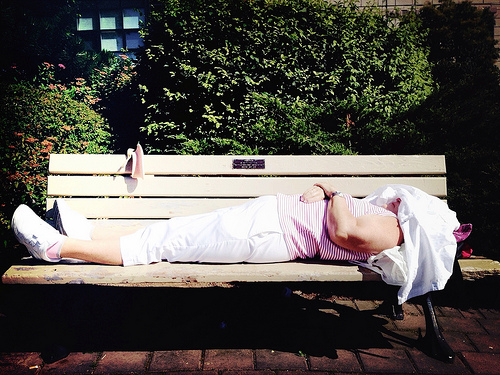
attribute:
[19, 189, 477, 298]
woman — resting, sleeping, tired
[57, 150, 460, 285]
bench — beige, wooden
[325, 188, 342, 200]
watch — silver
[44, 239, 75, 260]
socks — pink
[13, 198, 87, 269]
tennis shoes — white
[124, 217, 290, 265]
capris — white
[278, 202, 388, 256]
shirt — striped, pink, stripped, white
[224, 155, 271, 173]
plaque — small, black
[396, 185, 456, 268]
cloth — white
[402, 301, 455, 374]
legs — iron, black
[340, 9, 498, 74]
wall — tan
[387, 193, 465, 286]
jacket — white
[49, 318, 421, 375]
sidewalk — brick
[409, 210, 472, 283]
towel — white, pink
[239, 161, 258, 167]
lettering — white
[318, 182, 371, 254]
arms — folded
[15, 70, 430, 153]
bushes — big, green